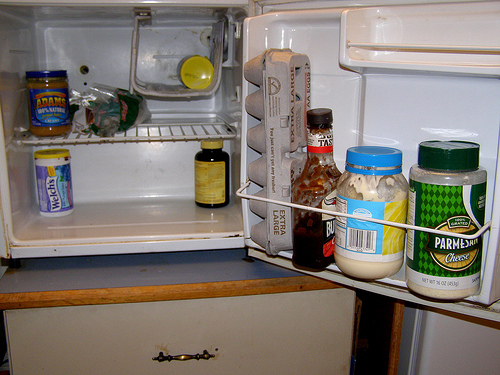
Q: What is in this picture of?
A: A refrigerator.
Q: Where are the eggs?
A: On the shelf door.